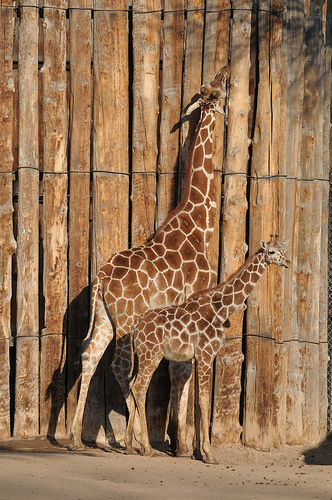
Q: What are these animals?
A: Giraffes.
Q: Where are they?
A: A zoo or refuge.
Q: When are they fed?
A: Twice daily.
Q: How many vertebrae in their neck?
A: 7.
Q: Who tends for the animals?
A: A zoo helper or refuge.